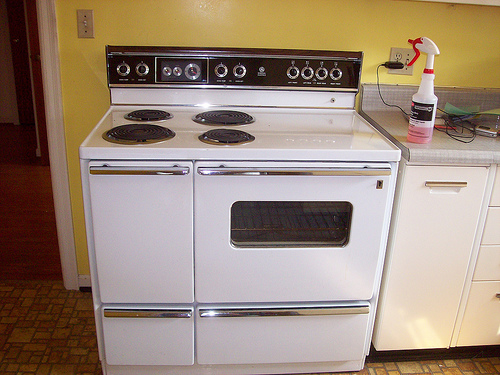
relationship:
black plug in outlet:
[385, 62, 407, 72] [385, 49, 423, 77]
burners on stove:
[105, 101, 258, 146] [83, 43, 410, 370]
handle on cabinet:
[424, 172, 475, 199] [375, 164, 494, 344]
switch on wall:
[76, 10, 95, 38] [56, 2, 486, 94]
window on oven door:
[231, 198, 354, 252] [195, 160, 387, 302]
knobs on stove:
[114, 57, 347, 84] [83, 43, 410, 370]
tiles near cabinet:
[361, 354, 500, 375] [375, 164, 494, 344]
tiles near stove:
[3, 287, 93, 368] [83, 43, 410, 370]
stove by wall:
[83, 43, 410, 370] [56, 2, 486, 94]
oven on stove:
[91, 154, 395, 302] [83, 43, 410, 370]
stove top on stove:
[87, 103, 391, 175] [83, 43, 410, 370]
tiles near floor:
[361, 354, 500, 375] [6, 166, 62, 280]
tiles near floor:
[3, 287, 93, 368] [6, 166, 62, 280]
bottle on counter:
[406, 35, 446, 141] [366, 86, 499, 169]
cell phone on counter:
[468, 118, 499, 147] [366, 86, 499, 169]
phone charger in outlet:
[382, 60, 479, 152] [385, 49, 423, 77]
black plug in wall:
[385, 62, 407, 72] [56, 2, 486, 94]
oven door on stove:
[195, 160, 387, 302] [83, 43, 410, 370]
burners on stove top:
[105, 101, 258, 146] [87, 103, 391, 175]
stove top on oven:
[87, 103, 391, 175] [91, 154, 395, 302]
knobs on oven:
[114, 57, 347, 84] [91, 154, 395, 302]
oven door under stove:
[195, 160, 387, 302] [83, 43, 410, 370]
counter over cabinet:
[366, 86, 499, 169] [375, 164, 494, 344]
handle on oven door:
[198, 156, 395, 186] [195, 160, 387, 302]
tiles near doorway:
[361, 354, 500, 375] [35, 1, 84, 292]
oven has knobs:
[91, 154, 395, 302] [114, 57, 347, 84]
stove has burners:
[83, 43, 410, 370] [105, 101, 258, 146]